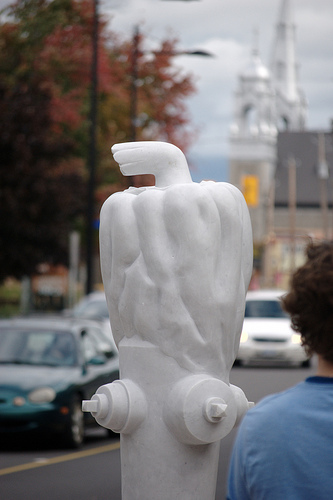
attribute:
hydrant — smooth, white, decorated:
[76, 138, 256, 498]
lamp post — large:
[125, 24, 212, 184]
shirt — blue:
[225, 374, 332, 499]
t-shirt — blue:
[222, 370, 332, 499]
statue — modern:
[88, 128, 253, 353]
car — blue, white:
[231, 289, 311, 370]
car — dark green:
[3, 312, 119, 449]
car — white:
[237, 291, 310, 368]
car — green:
[0, 314, 132, 450]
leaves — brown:
[21, 38, 97, 79]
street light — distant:
[139, 43, 225, 62]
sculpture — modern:
[85, 147, 228, 496]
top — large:
[92, 126, 254, 418]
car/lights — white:
[237, 288, 311, 368]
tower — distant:
[227, 16, 275, 242]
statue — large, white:
[139, 147, 230, 225]